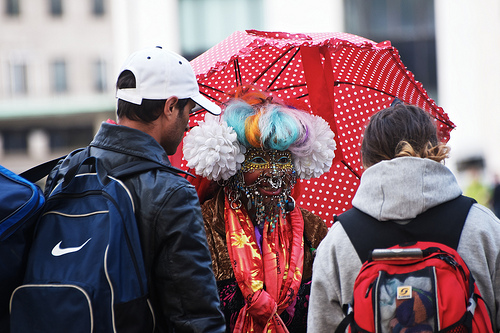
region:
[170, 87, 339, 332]
i [strongly] believe this is elaine davidson, 'the world's most pierced woman'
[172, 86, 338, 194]
she wears what may at first glance look like a crazy person's wig; however, it's not. it's, let's see, probaly a regular wig dyed multiple, largely pastel colours up front plus either two giant flowers or two parts of a feather boa bringing up the sides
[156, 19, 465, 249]
ruffles at the edge of red+white polka dot umbrella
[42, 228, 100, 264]
white nike logo on royal blue backpack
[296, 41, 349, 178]
red ribbon draping down from the side of the umbrella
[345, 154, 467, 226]
the pale grey hood of a pale grey hoodie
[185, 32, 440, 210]
the black ribs of the red [+white] umbrella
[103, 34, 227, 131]
a man in a white baseball cap stares @ elaine davidson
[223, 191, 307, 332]
a wide yellow on red scarf, which may have begun life a different garment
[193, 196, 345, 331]
elaine davidson also wears a brown burn out velvet jacket, along w/ something deep black w/ a magenta pattern beneath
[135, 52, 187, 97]
white hat on mans head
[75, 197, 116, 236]
blue book bag on mans back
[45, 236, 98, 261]
white nike sign on bag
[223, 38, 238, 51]
polka dots on umbrella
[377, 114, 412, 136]
mans hair is brown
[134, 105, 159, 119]
mans hair is black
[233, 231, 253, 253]
yellow leaf on scarf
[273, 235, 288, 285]
red and yellow scarf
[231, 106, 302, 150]
woman with colorful bang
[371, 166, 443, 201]
grey hood attatchment on hoody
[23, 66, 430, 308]
people standing in a group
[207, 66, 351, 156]
multi colored hair on person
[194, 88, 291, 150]
orange hair on top of head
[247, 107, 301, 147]
blue and purple hair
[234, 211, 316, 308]
red sash around person's neck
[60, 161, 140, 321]
blue nike backpack on back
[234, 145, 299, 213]
man with mask on his face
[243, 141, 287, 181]
yellow sequins all over mask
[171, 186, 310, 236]
piercings all over man's face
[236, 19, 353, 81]
umbrella with white polka dots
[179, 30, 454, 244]
red and white polka dot umbrella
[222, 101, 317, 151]
blue, range and purple pastel wig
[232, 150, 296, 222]
heaviliy decorated mask on person's face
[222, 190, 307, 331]
red and yellow scarf around person's neck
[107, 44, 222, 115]
white hat on man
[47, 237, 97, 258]
nike symbol on back pack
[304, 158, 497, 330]
gray hoodie on person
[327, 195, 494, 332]
red and black back pack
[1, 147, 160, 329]
dark blue and white nike back pack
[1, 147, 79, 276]
blue duffle bag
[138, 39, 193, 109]
Person wearing white hat.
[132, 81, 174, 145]
Person has short hair.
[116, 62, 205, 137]
Person has dark hair.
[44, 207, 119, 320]
White Nike swoosh on bag.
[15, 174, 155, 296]
Blue back pack on man's back.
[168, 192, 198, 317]
Man wearing dark jacket.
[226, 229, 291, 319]
Red and yellow scarf around person's neck.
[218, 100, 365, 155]
Person is wearing wig on head.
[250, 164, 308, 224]
Many piercings on person's face.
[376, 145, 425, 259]
Person wearing gray hoodie.